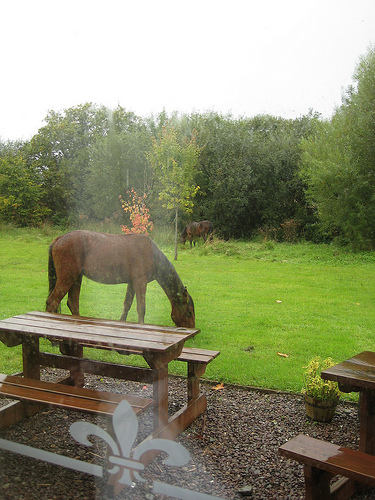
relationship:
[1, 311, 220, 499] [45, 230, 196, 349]
table next to horse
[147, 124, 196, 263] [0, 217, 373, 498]
tree in backyard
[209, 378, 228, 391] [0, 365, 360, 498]
leaf in rocks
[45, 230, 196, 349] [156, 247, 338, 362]
horse grazing grass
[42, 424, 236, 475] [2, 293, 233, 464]
rocks cover table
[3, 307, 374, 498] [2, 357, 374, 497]
benches sitting on stone patch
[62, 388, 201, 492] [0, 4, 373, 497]
decoration on window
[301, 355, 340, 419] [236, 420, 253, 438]
potted plant sits in rocks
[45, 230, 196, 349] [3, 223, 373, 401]
horse grazing on grass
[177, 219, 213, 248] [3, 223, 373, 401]
horse grazing on grass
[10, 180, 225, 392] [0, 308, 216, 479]
horse standing next to picnic bench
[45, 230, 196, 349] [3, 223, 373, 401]
horse eating grass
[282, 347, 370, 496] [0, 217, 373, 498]
bench in backyard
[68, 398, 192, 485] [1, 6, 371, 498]
fleur etched into glass